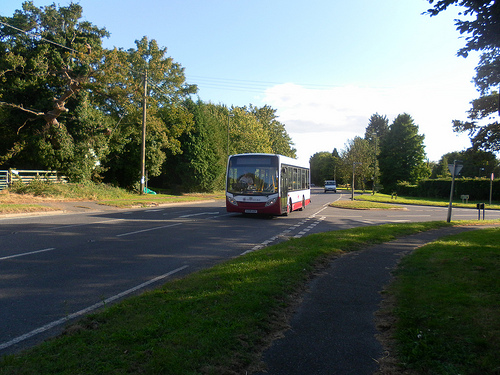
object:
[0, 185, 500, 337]
ground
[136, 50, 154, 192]
pole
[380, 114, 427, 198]
tree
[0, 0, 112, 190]
tree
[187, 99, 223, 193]
tree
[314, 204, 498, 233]
street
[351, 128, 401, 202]
wall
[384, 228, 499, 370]
mowed grass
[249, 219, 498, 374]
sidewalk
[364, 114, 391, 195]
tree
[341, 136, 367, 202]
tree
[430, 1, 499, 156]
tree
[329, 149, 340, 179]
tree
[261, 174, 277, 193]
driver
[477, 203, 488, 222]
sign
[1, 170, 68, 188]
fence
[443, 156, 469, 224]
sign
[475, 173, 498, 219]
mailbox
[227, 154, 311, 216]
bus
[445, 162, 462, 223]
pole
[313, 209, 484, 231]
corner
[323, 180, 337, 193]
van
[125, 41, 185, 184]
tree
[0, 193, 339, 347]
driveway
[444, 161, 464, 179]
back